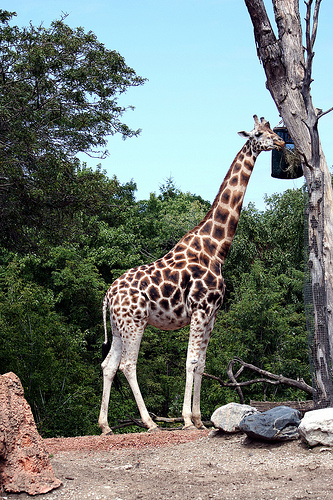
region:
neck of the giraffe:
[216, 165, 253, 210]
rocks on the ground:
[209, 403, 332, 441]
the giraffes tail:
[101, 302, 110, 346]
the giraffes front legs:
[183, 319, 210, 429]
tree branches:
[231, 351, 298, 396]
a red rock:
[3, 376, 61, 497]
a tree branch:
[306, 130, 332, 353]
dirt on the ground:
[83, 445, 265, 496]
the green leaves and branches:
[11, 26, 124, 163]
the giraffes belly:
[151, 305, 193, 330]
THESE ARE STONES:
[201, 402, 331, 448]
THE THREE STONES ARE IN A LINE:
[203, 392, 329, 448]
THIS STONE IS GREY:
[206, 396, 255, 434]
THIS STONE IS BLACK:
[237, 401, 304, 441]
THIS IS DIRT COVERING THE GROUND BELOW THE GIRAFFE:
[22, 426, 328, 494]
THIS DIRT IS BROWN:
[39, 433, 329, 497]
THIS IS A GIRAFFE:
[95, 109, 291, 440]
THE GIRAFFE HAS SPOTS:
[121, 264, 214, 316]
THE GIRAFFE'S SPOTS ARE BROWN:
[137, 266, 212, 313]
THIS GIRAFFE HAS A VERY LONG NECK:
[197, 148, 261, 278]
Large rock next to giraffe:
[210, 403, 257, 433]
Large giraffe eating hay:
[95, 111, 290, 433]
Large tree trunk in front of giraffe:
[244, 0, 331, 411]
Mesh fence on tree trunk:
[293, 156, 331, 405]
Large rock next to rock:
[238, 405, 302, 447]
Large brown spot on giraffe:
[211, 201, 229, 223]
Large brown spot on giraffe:
[209, 221, 225, 243]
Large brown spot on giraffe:
[198, 236, 218, 258]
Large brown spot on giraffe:
[217, 186, 234, 204]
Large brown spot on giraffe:
[237, 167, 251, 187]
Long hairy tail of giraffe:
[99, 290, 130, 414]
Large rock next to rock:
[210, 399, 256, 433]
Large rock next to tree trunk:
[237, 404, 298, 441]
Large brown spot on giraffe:
[228, 173, 237, 186]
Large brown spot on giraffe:
[198, 218, 212, 237]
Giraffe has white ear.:
[235, 120, 254, 151]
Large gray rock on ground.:
[298, 413, 327, 439]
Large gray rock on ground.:
[241, 402, 294, 432]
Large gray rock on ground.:
[213, 402, 256, 431]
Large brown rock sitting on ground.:
[6, 383, 57, 486]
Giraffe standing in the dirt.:
[75, 402, 210, 441]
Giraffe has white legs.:
[87, 381, 204, 412]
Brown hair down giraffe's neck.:
[208, 136, 247, 231]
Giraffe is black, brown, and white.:
[136, 209, 236, 330]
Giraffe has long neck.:
[200, 105, 270, 263]